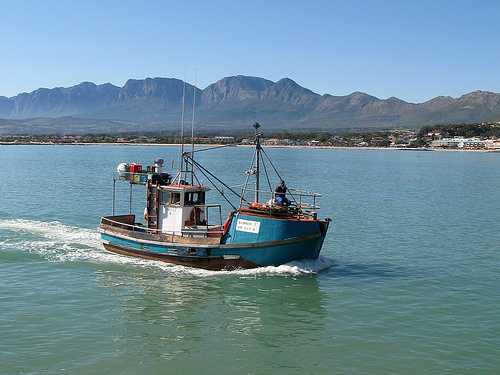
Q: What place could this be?
A: It is a sea.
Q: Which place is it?
A: It is a sea.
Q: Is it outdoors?
A: Yes, it is outdoors.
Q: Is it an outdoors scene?
A: Yes, it is outdoors.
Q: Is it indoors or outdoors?
A: It is outdoors.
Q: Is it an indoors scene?
A: No, it is outdoors.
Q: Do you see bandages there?
A: No, there are no bandages.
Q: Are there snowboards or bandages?
A: No, there are no bandages or snowboards.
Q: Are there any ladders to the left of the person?
A: Yes, there is a ladder to the left of the person.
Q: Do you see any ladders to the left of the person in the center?
A: Yes, there is a ladder to the left of the person.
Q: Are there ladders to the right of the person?
A: No, the ladder is to the left of the person.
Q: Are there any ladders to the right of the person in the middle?
A: No, the ladder is to the left of the person.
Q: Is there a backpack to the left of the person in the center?
A: No, there is a ladder to the left of the person.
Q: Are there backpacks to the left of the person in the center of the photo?
A: No, there is a ladder to the left of the person.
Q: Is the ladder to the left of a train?
A: No, the ladder is to the left of a person.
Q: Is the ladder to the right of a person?
A: No, the ladder is to the left of a person.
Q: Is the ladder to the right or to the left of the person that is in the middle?
A: The ladder is to the left of the person.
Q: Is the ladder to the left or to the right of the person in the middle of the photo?
A: The ladder is to the left of the person.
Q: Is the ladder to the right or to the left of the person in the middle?
A: The ladder is to the left of the person.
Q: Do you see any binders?
A: No, there are no binders.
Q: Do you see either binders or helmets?
A: No, there are no binders or helmets.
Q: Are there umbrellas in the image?
A: No, there are no umbrellas.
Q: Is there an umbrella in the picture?
A: No, there are no umbrellas.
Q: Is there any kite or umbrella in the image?
A: No, there are no umbrellas or kites.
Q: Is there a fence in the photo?
A: No, there are no fences.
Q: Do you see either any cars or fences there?
A: No, there are no fences or cars.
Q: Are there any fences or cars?
A: No, there are no fences or cars.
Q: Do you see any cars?
A: No, there are no cars.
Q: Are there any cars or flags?
A: No, there are no cars or flags.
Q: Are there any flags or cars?
A: No, there are no cars or flags.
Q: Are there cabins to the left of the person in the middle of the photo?
A: Yes, there is a cabin to the left of the person.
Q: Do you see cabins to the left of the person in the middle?
A: Yes, there is a cabin to the left of the person.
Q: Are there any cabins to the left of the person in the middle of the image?
A: Yes, there is a cabin to the left of the person.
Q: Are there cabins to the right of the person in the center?
A: No, the cabin is to the left of the person.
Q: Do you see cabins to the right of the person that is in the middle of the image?
A: No, the cabin is to the left of the person.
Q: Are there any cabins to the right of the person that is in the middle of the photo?
A: No, the cabin is to the left of the person.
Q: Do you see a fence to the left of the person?
A: No, there is a cabin to the left of the person.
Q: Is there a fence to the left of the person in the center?
A: No, there is a cabin to the left of the person.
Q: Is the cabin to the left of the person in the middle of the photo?
A: Yes, the cabin is to the left of the person.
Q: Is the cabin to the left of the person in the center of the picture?
A: Yes, the cabin is to the left of the person.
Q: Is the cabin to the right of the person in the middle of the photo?
A: No, the cabin is to the left of the person.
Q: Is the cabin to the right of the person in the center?
A: No, the cabin is to the left of the person.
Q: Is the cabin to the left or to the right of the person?
A: The cabin is to the left of the person.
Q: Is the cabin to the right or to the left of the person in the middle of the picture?
A: The cabin is to the left of the person.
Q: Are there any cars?
A: No, there are no cars.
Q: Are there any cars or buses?
A: No, there are no cars or buses.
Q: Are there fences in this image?
A: No, there are no fences.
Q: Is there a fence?
A: No, there are no fences.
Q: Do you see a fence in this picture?
A: No, there are no fences.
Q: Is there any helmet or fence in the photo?
A: No, there are no fences or helmets.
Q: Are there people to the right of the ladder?
A: Yes, there is a person to the right of the ladder.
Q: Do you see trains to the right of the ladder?
A: No, there is a person to the right of the ladder.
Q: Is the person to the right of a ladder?
A: Yes, the person is to the right of a ladder.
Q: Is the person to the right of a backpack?
A: No, the person is to the right of a ladder.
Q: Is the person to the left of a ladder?
A: No, the person is to the right of a ladder.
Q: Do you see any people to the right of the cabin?
A: Yes, there is a person to the right of the cabin.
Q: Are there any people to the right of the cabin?
A: Yes, there is a person to the right of the cabin.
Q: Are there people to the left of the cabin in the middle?
A: No, the person is to the right of the cabin.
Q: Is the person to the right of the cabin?
A: Yes, the person is to the right of the cabin.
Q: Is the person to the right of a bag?
A: No, the person is to the right of the cabin.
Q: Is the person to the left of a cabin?
A: No, the person is to the right of a cabin.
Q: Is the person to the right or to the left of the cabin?
A: The person is to the right of the cabin.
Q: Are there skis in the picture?
A: No, there are no skis.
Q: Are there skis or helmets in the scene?
A: No, there are no skis or helmets.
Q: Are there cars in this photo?
A: No, there are no cars.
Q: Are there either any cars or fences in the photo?
A: No, there are no cars or fences.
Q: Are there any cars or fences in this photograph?
A: No, there are no cars or fences.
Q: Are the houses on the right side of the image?
A: Yes, the houses are on the right of the image.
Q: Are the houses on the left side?
A: No, the houses are on the right of the image.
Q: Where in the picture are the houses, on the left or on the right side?
A: The houses are on the right of the image.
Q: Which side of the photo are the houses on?
A: The houses are on the right of the image.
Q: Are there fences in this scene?
A: No, there are no fences.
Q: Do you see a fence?
A: No, there are no fences.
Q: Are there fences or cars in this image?
A: No, there are no fences or cars.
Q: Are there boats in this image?
A: Yes, there is a boat.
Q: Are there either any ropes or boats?
A: Yes, there is a boat.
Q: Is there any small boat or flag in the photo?
A: Yes, there is a small boat.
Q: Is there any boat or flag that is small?
A: Yes, the boat is small.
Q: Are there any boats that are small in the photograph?
A: Yes, there is a small boat.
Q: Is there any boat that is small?
A: Yes, there is a boat that is small.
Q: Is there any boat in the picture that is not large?
A: Yes, there is a small boat.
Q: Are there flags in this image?
A: No, there are no flags.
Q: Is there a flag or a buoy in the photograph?
A: No, there are no flags or buoys.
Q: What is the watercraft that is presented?
A: The watercraft is a boat.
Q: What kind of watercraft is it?
A: The watercraft is a boat.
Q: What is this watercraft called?
A: This is a boat.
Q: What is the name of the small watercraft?
A: The watercraft is a boat.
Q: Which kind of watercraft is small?
A: The watercraft is a boat.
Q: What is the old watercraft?
A: The watercraft is a boat.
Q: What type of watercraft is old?
A: The watercraft is a boat.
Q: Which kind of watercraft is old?
A: The watercraft is a boat.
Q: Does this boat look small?
A: Yes, the boat is small.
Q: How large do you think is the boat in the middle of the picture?
A: The boat is small.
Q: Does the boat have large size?
A: No, the boat is small.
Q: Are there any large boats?
A: No, there is a boat but it is small.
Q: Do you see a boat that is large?
A: No, there is a boat but it is small.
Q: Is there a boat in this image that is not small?
A: No, there is a boat but it is small.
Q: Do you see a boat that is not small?
A: No, there is a boat but it is small.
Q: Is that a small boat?
A: Yes, that is a small boat.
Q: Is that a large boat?
A: No, that is a small boat.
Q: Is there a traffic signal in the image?
A: No, there are no traffic lights.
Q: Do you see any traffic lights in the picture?
A: No, there are no traffic lights.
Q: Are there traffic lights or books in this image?
A: No, there are no traffic lights or books.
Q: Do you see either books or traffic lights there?
A: No, there are no traffic lights or books.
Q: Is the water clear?
A: Yes, the water is clear.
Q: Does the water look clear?
A: Yes, the water is clear.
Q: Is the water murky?
A: No, the water is clear.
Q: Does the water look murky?
A: No, the water is clear.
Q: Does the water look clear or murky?
A: The water is clear.